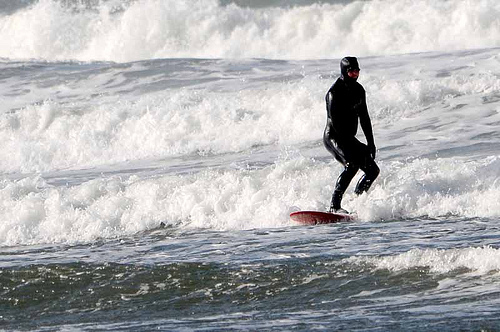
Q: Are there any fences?
A: No, there are no fences.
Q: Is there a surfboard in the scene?
A: Yes, there is a surfboard.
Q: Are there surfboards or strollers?
A: Yes, there is a surfboard.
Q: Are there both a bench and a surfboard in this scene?
A: No, there is a surfboard but no benches.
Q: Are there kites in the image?
A: No, there are no kites.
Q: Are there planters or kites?
A: No, there are no kites or planters.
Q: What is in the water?
A: The surf board is in the water.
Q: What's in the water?
A: The surf board is in the water.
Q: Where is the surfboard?
A: The surfboard is in the water.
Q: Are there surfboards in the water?
A: Yes, there is a surfboard in the water.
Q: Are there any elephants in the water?
A: No, there is a surfboard in the water.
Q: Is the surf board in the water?
A: Yes, the surf board is in the water.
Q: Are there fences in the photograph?
A: No, there are no fences.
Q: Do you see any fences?
A: No, there are no fences.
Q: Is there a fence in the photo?
A: No, there are no fences.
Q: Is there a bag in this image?
A: No, there are no bags.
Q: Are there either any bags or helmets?
A: No, there are no bags or helmets.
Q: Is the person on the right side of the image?
A: Yes, the person is on the right of the image.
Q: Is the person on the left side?
A: No, the person is on the right of the image.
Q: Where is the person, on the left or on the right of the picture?
A: The person is on the right of the image.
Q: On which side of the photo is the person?
A: The person is on the right of the image.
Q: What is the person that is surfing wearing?
A: The person is wearing goggles.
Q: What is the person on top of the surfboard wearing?
A: The person is wearing goggles.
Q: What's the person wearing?
A: The person is wearing goggles.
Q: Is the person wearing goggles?
A: Yes, the person is wearing goggles.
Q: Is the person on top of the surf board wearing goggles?
A: Yes, the person is wearing goggles.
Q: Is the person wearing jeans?
A: No, the person is wearing goggles.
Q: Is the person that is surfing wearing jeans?
A: No, the person is wearing goggles.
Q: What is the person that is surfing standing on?
A: The person is standing on the surfboard.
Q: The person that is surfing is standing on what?
A: The person is standing on the surfboard.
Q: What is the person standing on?
A: The person is standing on the surfboard.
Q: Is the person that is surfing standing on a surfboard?
A: Yes, the person is standing on a surfboard.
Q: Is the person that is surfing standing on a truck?
A: No, the person is standing on a surfboard.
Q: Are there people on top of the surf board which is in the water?
A: Yes, there is a person on top of the surfboard.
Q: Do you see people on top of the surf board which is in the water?
A: Yes, there is a person on top of the surfboard.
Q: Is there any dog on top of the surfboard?
A: No, there is a person on top of the surfboard.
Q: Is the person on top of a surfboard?
A: Yes, the person is on top of a surfboard.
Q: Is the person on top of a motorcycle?
A: No, the person is on top of a surfboard.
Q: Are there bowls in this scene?
A: No, there are no bowls.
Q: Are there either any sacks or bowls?
A: No, there are no bowls or sacks.